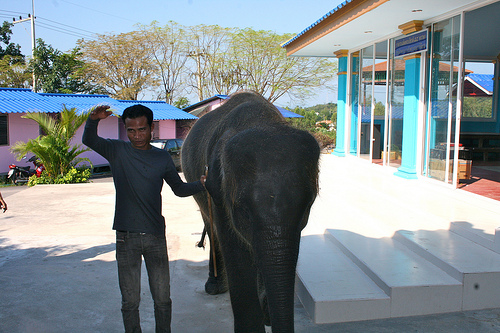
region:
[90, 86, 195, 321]
man wearing blue shirt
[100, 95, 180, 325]
man wearing blue jeans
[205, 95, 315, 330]
elephant near white stairs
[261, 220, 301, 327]
trunk of an elephant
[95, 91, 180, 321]
man stands near elephant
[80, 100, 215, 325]
man touches an elephant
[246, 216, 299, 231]
wrinkle on elephant trunk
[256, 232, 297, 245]
wrinkle on elephant trunk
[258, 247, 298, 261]
wrinkle on elephant trunk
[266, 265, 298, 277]
wrinkle on elephant trunk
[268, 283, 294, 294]
wrinkle on elephant trunk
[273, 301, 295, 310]
wrinkle on elephant trunk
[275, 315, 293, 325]
wrinkle on elephant trunk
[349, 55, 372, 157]
glass window on building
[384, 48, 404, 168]
glass window on building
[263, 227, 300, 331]
The trunk of the elephant.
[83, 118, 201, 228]
The sweater the man is wearing.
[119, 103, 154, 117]
The short hair of the man.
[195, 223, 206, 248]
The tail of the elephant.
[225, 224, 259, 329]
The front left leg of the elephant.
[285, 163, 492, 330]
The white stairs leading to the house.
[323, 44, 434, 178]
The blue pillars of the building.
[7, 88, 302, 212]
The houses in the background.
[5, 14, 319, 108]
The trees in the distance.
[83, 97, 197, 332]
man wearing dark grey shirt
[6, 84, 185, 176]
pinl building with blue roof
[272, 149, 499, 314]
white stairs next to elephant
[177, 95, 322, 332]
small gray elephant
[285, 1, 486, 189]
blue building with white trim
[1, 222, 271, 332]
shadow on the pavement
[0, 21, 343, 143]
trees behind the pink building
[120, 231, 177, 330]
jeans the man is wearing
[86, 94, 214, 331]
man saluting next to elephant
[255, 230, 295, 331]
The trunk of the elephant.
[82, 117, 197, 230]
The shirt the man is wearing.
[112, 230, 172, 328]
The pants the man is wearing.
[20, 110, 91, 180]
The plant in front of the house.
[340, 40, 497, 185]
The windows on the right.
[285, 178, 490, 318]
The stairs leading to the open door.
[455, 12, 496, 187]
The open door on the right.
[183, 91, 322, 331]
a gray african elephant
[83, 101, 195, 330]
a man standing next to an elephant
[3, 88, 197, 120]
the blue metal roof of a building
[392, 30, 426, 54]
a blue and white sign on a building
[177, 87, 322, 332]
a baby grey elephant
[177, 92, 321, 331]
a small elephant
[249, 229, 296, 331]
the trunk on an elephant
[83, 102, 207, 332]
a man standing next to an elephant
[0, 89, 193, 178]
a pink building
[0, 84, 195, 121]
a blue roof on a pink building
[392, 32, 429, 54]
a sign on a building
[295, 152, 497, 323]
stairs leading to a blue building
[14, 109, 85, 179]
a large bush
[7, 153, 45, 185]
a parked moped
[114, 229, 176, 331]
a pair of jeans on a man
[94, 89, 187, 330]
A short man in a blue shirt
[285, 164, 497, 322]
a white set of stairs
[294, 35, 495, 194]
a building which is colored a light blue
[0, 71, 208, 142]
a blue awning of a building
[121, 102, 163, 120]
black hair on a mans head